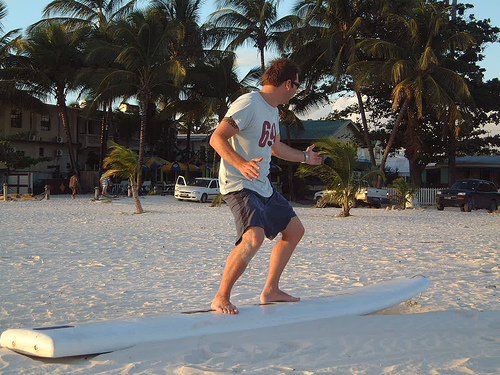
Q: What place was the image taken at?
A: It was taken at the beach.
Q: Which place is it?
A: It is a beach.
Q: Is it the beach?
A: Yes, it is the beach.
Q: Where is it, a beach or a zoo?
A: It is a beach.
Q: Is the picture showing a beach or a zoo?
A: It is showing a beach.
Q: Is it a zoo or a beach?
A: It is a beach.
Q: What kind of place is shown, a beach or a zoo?
A: It is a beach.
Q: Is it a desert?
A: No, it is a beach.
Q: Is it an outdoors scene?
A: Yes, it is outdoors.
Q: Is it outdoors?
A: Yes, it is outdoors.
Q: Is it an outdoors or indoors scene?
A: It is outdoors.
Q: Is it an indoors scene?
A: No, it is outdoors.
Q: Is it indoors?
A: No, it is outdoors.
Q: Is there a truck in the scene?
A: Yes, there is a truck.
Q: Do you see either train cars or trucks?
A: Yes, there is a truck.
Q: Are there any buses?
A: No, there are no buses.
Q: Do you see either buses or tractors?
A: No, there are no buses or tractors.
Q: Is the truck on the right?
A: Yes, the truck is on the right of the image.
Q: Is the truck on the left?
A: No, the truck is on the right of the image.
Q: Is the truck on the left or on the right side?
A: The truck is on the right of the image.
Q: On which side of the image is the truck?
A: The truck is on the right of the image.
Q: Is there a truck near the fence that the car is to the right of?
A: Yes, there is a truck near the fence.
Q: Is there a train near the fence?
A: No, there is a truck near the fence.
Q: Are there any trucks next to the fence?
A: Yes, there is a truck next to the fence.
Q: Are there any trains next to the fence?
A: No, there is a truck next to the fence.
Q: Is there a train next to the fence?
A: No, there is a truck next to the fence.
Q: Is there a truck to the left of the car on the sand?
A: Yes, there is a truck to the left of the car.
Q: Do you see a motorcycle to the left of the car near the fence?
A: No, there is a truck to the left of the car.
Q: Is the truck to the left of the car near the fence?
A: Yes, the truck is to the left of the car.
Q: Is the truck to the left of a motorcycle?
A: No, the truck is to the left of the car.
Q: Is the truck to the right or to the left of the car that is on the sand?
A: The truck is to the left of the car.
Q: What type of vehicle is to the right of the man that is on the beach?
A: The vehicle is a truck.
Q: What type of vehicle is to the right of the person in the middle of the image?
A: The vehicle is a truck.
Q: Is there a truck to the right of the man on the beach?
A: Yes, there is a truck to the right of the man.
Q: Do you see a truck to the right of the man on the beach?
A: Yes, there is a truck to the right of the man.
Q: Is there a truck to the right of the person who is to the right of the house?
A: Yes, there is a truck to the right of the man.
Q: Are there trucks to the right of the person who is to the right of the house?
A: Yes, there is a truck to the right of the man.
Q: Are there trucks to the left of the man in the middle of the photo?
A: No, the truck is to the right of the man.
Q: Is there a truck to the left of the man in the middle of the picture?
A: No, the truck is to the right of the man.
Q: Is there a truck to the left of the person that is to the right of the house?
A: No, the truck is to the right of the man.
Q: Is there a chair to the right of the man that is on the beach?
A: No, there is a truck to the right of the man.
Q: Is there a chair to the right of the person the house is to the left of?
A: No, there is a truck to the right of the man.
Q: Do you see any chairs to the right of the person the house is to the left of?
A: No, there is a truck to the right of the man.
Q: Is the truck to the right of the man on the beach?
A: Yes, the truck is to the right of the man.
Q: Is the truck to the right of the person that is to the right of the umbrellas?
A: Yes, the truck is to the right of the man.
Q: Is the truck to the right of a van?
A: No, the truck is to the right of the man.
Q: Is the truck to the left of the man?
A: No, the truck is to the right of the man.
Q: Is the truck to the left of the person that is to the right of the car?
A: No, the truck is to the right of the man.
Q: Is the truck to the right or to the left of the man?
A: The truck is to the right of the man.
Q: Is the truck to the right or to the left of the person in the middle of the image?
A: The truck is to the right of the man.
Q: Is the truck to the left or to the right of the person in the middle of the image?
A: The truck is to the right of the man.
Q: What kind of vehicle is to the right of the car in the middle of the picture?
A: The vehicle is a truck.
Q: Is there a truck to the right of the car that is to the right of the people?
A: Yes, there is a truck to the right of the car.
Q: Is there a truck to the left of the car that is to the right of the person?
A: No, the truck is to the right of the car.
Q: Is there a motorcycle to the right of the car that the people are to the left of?
A: No, there is a truck to the right of the car.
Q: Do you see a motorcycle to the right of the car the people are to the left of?
A: No, there is a truck to the right of the car.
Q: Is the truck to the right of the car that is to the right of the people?
A: Yes, the truck is to the right of the car.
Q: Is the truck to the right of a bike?
A: No, the truck is to the right of the car.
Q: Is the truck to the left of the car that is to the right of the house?
A: No, the truck is to the right of the car.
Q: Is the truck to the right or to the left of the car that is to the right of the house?
A: The truck is to the right of the car.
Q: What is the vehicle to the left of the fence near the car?
A: The vehicle is a truck.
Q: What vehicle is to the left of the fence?
A: The vehicle is a truck.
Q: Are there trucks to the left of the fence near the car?
A: Yes, there is a truck to the left of the fence.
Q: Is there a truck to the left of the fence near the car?
A: Yes, there is a truck to the left of the fence.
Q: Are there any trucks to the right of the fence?
A: No, the truck is to the left of the fence.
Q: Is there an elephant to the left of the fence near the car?
A: No, there is a truck to the left of the fence.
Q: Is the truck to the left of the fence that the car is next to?
A: Yes, the truck is to the left of the fence.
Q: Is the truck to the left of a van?
A: No, the truck is to the left of the fence.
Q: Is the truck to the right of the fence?
A: No, the truck is to the left of the fence.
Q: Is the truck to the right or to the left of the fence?
A: The truck is to the left of the fence.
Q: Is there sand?
A: Yes, there is sand.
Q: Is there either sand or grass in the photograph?
A: Yes, there is sand.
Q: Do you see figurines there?
A: No, there are no figurines.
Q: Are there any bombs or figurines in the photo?
A: No, there are no figurines or bombs.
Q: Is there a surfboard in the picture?
A: Yes, there is a surfboard.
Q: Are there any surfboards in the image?
A: Yes, there is a surfboard.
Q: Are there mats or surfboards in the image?
A: Yes, there is a surfboard.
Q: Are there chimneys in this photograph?
A: No, there are no chimneys.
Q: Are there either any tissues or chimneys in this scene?
A: No, there are no chimneys or tissues.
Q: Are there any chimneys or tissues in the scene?
A: No, there are no chimneys or tissues.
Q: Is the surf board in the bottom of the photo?
A: Yes, the surf board is in the bottom of the image.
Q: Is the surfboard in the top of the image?
A: No, the surfboard is in the bottom of the image.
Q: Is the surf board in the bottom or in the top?
A: The surf board is in the bottom of the image.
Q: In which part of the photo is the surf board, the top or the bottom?
A: The surf board is in the bottom of the image.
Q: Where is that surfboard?
A: The surfboard is in the sand.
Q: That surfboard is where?
A: The surfboard is in the sand.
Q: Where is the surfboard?
A: The surfboard is in the sand.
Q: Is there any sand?
A: Yes, there is sand.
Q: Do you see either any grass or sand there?
A: Yes, there is sand.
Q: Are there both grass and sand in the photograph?
A: No, there is sand but no grass.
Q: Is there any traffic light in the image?
A: No, there are no traffic lights.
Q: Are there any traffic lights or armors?
A: No, there are no traffic lights or armors.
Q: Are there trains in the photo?
A: No, there are no trains.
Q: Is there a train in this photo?
A: No, there are no trains.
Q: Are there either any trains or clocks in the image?
A: No, there are no trains or clocks.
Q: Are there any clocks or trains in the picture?
A: No, there are no trains or clocks.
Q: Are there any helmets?
A: No, there are no helmets.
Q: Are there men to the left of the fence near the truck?
A: Yes, there is a man to the left of the fence.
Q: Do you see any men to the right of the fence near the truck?
A: No, the man is to the left of the fence.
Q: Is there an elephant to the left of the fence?
A: No, there is a man to the left of the fence.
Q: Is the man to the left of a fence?
A: Yes, the man is to the left of a fence.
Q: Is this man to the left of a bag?
A: No, the man is to the left of a fence.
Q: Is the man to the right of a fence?
A: No, the man is to the left of a fence.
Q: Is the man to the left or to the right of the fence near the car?
A: The man is to the left of the fence.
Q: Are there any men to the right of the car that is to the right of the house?
A: Yes, there is a man to the right of the car.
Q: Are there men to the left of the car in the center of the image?
A: No, the man is to the right of the car.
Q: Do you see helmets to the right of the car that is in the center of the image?
A: No, there is a man to the right of the car.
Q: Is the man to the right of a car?
A: Yes, the man is to the right of a car.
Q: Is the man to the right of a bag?
A: No, the man is to the right of a car.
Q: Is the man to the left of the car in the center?
A: No, the man is to the right of the car.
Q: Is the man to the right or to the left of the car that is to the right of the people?
A: The man is to the right of the car.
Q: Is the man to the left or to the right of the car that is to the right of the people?
A: The man is to the right of the car.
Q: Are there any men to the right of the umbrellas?
A: Yes, there is a man to the right of the umbrellas.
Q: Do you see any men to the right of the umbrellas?
A: Yes, there is a man to the right of the umbrellas.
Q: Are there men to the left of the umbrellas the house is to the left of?
A: No, the man is to the right of the umbrellas.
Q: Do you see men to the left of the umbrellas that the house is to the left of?
A: No, the man is to the right of the umbrellas.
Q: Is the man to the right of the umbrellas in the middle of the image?
A: Yes, the man is to the right of the umbrellas.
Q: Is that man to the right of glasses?
A: No, the man is to the right of the umbrellas.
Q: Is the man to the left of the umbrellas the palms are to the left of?
A: No, the man is to the right of the umbrellas.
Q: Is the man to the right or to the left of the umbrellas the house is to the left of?
A: The man is to the right of the umbrellas.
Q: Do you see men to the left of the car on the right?
A: Yes, there is a man to the left of the car.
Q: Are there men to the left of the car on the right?
A: Yes, there is a man to the left of the car.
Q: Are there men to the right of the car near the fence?
A: No, the man is to the left of the car.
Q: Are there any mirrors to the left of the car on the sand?
A: No, there is a man to the left of the car.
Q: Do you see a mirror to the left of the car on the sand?
A: No, there is a man to the left of the car.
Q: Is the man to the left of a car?
A: Yes, the man is to the left of a car.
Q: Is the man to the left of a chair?
A: No, the man is to the left of a car.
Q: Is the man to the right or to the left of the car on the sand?
A: The man is to the left of the car.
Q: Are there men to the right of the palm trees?
A: Yes, there is a man to the right of the palm trees.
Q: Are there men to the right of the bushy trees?
A: Yes, there is a man to the right of the palm trees.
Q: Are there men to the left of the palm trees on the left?
A: No, the man is to the right of the palm trees.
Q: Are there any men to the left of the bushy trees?
A: No, the man is to the right of the palm trees.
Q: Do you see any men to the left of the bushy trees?
A: No, the man is to the right of the palm trees.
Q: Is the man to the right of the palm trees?
A: Yes, the man is to the right of the palm trees.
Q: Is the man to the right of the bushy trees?
A: Yes, the man is to the right of the palm trees.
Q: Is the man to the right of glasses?
A: No, the man is to the right of the palm trees.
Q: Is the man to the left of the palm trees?
A: No, the man is to the right of the palm trees.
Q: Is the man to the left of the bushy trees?
A: No, the man is to the right of the palm trees.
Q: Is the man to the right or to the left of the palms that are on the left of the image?
A: The man is to the right of the palms.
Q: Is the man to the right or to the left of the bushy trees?
A: The man is to the right of the palms.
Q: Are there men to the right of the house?
A: Yes, there is a man to the right of the house.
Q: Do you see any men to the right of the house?
A: Yes, there is a man to the right of the house.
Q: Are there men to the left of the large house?
A: No, the man is to the right of the house.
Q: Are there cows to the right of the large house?
A: No, there is a man to the right of the house.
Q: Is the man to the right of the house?
A: Yes, the man is to the right of the house.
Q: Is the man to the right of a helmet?
A: No, the man is to the right of the house.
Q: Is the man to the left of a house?
A: No, the man is to the right of a house.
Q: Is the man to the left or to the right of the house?
A: The man is to the right of the house.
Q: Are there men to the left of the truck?
A: Yes, there is a man to the left of the truck.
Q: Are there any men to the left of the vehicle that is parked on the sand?
A: Yes, there is a man to the left of the truck.